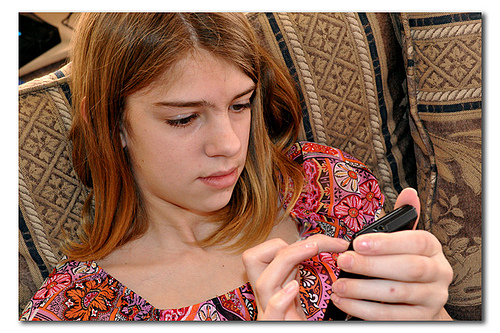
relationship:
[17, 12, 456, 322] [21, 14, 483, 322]
girl on couch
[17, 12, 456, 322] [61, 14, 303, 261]
girl has brown hair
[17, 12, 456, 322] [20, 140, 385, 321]
girl wearing shirt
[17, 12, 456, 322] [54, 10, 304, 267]
girl has hair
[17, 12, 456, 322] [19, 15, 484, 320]
girl has hair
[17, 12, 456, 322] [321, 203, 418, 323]
girl using cellphone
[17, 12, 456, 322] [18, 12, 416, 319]
girl leaning on pillow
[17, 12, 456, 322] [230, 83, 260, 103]
girl has eyebrow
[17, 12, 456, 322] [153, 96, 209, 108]
girl has eyebrow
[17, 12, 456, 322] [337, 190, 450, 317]
girl typing on phone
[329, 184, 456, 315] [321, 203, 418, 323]
hand holding cellphone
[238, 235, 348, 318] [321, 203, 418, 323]
hand holding cellphone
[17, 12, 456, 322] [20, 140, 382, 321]
girl wearing dress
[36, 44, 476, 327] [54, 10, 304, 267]
girl has hair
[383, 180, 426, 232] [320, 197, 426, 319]
thumb above object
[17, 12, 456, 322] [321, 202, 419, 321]
girl looking at cellphone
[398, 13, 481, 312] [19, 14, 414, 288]
pillow behind pillow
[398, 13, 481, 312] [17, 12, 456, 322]
pillow behind girl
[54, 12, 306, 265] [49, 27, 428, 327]
brown hair on girl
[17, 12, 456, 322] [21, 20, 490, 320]
girl leaning back on pillows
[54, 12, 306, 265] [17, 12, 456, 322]
brown hair on girl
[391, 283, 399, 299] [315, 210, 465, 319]
mark on finger